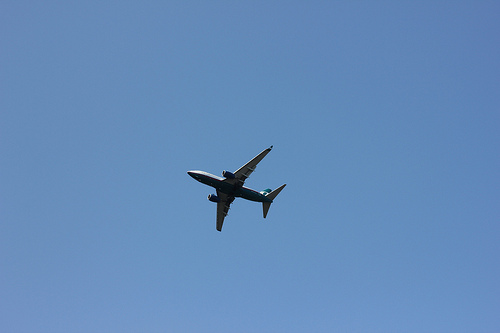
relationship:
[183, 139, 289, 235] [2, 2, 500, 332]
airplane in sky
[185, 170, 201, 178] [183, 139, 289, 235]
tip on airplane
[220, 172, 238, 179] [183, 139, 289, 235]
engine on airplane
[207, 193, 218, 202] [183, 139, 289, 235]
engine on airplane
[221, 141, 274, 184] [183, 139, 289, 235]
wing on a airplane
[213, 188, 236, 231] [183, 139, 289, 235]
wing on a airplane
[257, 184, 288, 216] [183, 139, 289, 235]
tail on airplane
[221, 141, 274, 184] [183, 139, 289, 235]
wing on airplane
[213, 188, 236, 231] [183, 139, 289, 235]
wing on airplane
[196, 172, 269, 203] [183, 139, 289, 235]
body on airplane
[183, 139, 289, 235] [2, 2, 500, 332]
plane in sky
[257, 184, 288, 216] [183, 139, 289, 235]
tail of airplane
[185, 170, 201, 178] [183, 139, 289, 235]
tip of airplane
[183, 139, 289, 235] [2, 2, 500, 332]
airplane flying in sky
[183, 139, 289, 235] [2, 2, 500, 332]
airplane soaring in sky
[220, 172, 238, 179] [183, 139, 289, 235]
engine on an airplane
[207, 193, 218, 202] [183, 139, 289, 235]
engine on an airplane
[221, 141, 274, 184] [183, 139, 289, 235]
wing of an airplane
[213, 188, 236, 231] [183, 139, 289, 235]
wing of an airplane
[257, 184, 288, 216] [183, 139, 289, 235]
tail of an airplane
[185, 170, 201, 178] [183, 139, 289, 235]
tip of a airplane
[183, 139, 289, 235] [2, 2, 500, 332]
airplane flying in a sky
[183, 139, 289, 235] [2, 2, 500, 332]
airplane soaring through sky